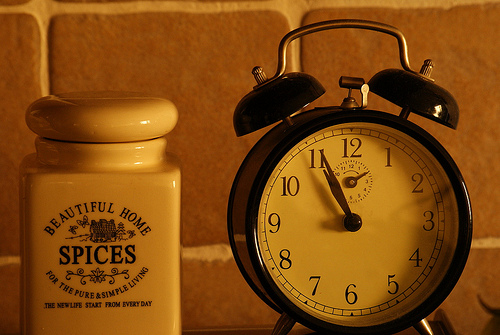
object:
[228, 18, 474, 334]
alarm clock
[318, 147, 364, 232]
hands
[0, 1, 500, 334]
tiles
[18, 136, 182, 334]
jar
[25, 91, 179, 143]
lid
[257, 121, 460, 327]
face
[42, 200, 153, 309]
letters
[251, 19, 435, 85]
handle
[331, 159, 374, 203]
small clock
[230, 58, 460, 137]
bells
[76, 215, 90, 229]
butterfly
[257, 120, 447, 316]
10:56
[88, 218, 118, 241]
building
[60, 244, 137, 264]
spices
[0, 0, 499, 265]
grout